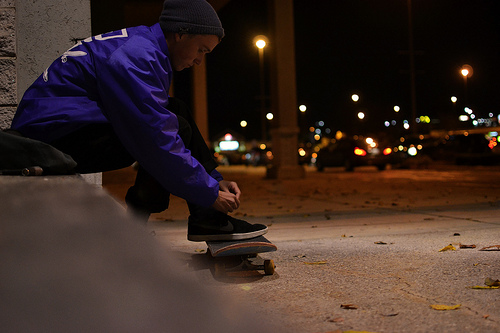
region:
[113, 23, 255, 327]
a man tying his shoe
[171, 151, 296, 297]
a man with his foot on a skateboard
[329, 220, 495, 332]
brown and yellow leaves on the ground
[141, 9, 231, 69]
a man wearing a hat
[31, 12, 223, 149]
a man wearing a purple and white jacket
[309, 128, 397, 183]
a vehicle on a road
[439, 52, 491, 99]
a street light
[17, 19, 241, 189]
a man sitting down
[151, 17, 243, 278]
a man wearing a black shoe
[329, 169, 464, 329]
a concrete sidewalk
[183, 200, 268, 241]
Black tennis shoe on foot.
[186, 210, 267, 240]
White nike mark on shoe.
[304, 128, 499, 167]
Cars on the road.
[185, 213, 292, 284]
Skateboard on the pavement.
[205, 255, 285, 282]
Brown wheels on the skateboard.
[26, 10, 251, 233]
Blue jacket on boy.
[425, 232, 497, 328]
Yellow leaves on the ground.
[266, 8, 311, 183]
Stone pillars under bridge.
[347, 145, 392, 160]
Red tail lights on the car.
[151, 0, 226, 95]
The boy is wearing a hat.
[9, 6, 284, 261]
person sitting down on the sidewalk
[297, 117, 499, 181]
cars on the street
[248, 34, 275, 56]
light shining on top of the pole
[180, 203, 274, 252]
foot resting on the skateboard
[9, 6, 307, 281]
person tying their shoe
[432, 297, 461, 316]
yellow leaf on the ground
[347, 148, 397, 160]
red lights shining on the back of the car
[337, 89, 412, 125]
lights shining in the dark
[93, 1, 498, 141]
the sky is pitch black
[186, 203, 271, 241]
white and black shoe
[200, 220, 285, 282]
skateboard on the sidewalk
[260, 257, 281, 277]
wheel on a skateboard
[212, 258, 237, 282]
wheel on a skateboard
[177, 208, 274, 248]
black and white shoe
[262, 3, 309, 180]
column on the sidewalk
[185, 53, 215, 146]
column on the sidewalk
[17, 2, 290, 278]
person sitting on the curb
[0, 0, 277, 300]
person wearing blue jacket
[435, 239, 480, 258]
leaf on the sidewalk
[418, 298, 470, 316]
leaf on the sidewalk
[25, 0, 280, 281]
man with his foot on a skateboard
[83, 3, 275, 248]
man tying his shoe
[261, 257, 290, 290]
wheel on the skateboard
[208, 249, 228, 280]
wheel on the skateboard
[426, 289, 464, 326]
leaf on the ground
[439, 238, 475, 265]
leaf on the ground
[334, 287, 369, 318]
leaf on the ground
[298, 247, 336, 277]
leaf on the ground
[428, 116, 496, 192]
car on the street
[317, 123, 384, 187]
car on the street